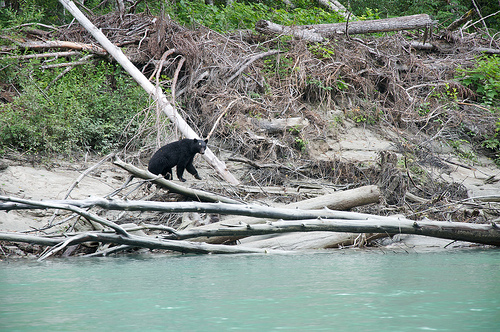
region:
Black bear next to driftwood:
[137, 132, 224, 192]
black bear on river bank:
[135, 130, 242, 265]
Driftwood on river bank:
[16, 185, 451, 270]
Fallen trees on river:
[217, 136, 453, 271]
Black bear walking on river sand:
[103, 105, 300, 210]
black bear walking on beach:
[103, 117, 275, 264]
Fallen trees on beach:
[265, 88, 499, 271]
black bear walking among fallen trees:
[133, 109, 413, 272]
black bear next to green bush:
[84, 107, 241, 190]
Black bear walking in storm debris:
[125, 114, 320, 211]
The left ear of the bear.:
[192, 137, 196, 142]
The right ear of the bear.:
[202, 137, 209, 142]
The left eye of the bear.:
[198, 142, 202, 148]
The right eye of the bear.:
[202, 145, 207, 147]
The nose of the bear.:
[200, 149, 203, 154]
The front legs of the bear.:
[177, 156, 202, 183]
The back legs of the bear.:
[158, 164, 173, 179]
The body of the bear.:
[149, 135, 187, 172]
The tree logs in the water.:
[5, 150, 498, 296]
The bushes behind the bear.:
[7, 12, 224, 155]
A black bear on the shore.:
[148, 138, 208, 184]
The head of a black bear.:
[193, 134, 209, 154]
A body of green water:
[0, 248, 499, 328]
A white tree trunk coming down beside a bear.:
[59, 0, 240, 185]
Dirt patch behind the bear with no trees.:
[3, 156, 124, 196]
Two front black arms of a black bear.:
[174, 155, 201, 183]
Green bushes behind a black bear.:
[3, 63, 143, 155]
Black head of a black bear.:
[193, 134, 209, 156]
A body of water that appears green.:
[0, 247, 499, 330]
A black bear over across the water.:
[148, 136, 207, 182]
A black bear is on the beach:
[116, 108, 330, 258]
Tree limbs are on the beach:
[46, 93, 444, 290]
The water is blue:
[65, 257, 210, 330]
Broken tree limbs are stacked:
[40, 158, 453, 272]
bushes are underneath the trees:
[36, 70, 178, 175]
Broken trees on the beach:
[132, 25, 473, 225]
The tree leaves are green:
[190, 7, 476, 68]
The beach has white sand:
[14, 173, 165, 285]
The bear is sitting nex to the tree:
[135, 132, 244, 199]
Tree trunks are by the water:
[232, 195, 465, 300]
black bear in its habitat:
[11, 12, 473, 314]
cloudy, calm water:
[70, 270, 467, 325]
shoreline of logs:
[70, 210, 302, 257]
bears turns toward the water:
[145, 131, 210, 178]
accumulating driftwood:
[310, 177, 495, 242]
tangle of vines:
[160, 21, 230, 93]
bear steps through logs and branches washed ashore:
[25, 7, 422, 242]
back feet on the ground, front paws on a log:
[142, 135, 204, 191]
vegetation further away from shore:
[190, 0, 380, 31]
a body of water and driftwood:
[1, 205, 493, 325]